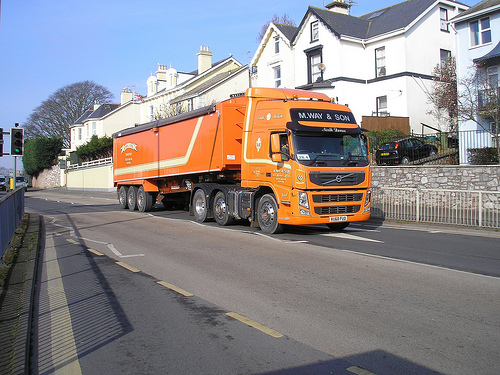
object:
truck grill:
[370, 186, 499, 233]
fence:
[65, 157, 114, 192]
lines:
[225, 313, 287, 343]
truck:
[111, 86, 372, 234]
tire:
[192, 189, 206, 222]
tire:
[118, 186, 128, 209]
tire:
[126, 186, 137, 211]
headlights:
[298, 191, 310, 208]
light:
[299, 209, 310, 216]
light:
[365, 190, 372, 206]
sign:
[119, 142, 138, 154]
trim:
[303, 45, 325, 84]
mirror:
[271, 132, 289, 161]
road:
[0, 188, 500, 375]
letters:
[298, 113, 350, 121]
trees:
[21, 81, 117, 154]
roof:
[249, 2, 466, 72]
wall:
[363, 162, 498, 227]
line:
[114, 114, 204, 176]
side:
[112, 87, 299, 233]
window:
[269, 130, 291, 161]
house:
[251, 0, 471, 159]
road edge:
[0, 211, 43, 373]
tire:
[213, 192, 234, 226]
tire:
[257, 193, 281, 235]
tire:
[136, 186, 152, 212]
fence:
[369, 186, 500, 228]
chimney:
[196, 45, 215, 74]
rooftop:
[169, 64, 248, 105]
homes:
[62, 0, 497, 161]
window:
[303, 46, 324, 83]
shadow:
[344, 208, 384, 234]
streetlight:
[9, 128, 24, 157]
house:
[446, 1, 500, 164]